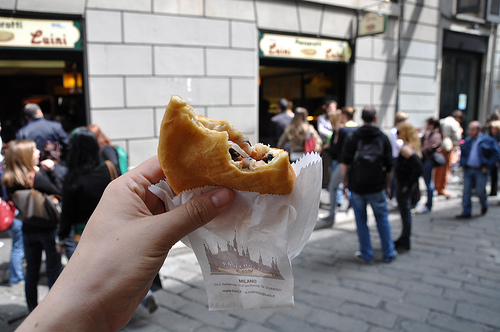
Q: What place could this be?
A: It is a street.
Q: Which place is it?
A: It is a street.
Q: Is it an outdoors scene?
A: Yes, it is outdoors.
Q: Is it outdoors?
A: Yes, it is outdoors.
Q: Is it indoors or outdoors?
A: It is outdoors.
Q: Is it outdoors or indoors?
A: It is outdoors.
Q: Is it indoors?
A: No, it is outdoors.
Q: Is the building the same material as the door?
A: No, the building is made of concrete and the door is made of glass.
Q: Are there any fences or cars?
A: No, there are no fences or cars.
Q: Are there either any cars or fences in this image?
A: No, there are no fences or cars.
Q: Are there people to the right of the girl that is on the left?
A: Yes, there is a person to the right of the girl.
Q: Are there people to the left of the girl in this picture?
A: No, the person is to the right of the girl.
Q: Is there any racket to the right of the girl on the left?
A: No, there is a person to the right of the girl.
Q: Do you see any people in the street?
A: Yes, there is a person in the street.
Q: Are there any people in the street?
A: Yes, there is a person in the street.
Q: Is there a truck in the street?
A: No, there is a person in the street.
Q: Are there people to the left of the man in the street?
A: Yes, there is a person to the left of the man.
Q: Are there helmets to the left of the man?
A: No, there is a person to the left of the man.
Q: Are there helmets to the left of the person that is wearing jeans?
A: No, there is a person to the left of the man.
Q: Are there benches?
A: No, there are no benches.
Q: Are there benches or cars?
A: No, there are no benches or cars.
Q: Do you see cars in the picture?
A: No, there are no cars.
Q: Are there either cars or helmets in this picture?
A: No, there are no cars or helmets.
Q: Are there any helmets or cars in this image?
A: No, there are no cars or helmets.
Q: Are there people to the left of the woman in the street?
A: Yes, there is a person to the left of the woman.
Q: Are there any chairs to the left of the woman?
A: No, there is a person to the left of the woman.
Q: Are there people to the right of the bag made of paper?
A: Yes, there is a person to the right of the bag.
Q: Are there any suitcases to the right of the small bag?
A: No, there is a person to the right of the bag.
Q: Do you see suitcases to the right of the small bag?
A: No, there is a person to the right of the bag.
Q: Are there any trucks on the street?
A: No, there is a person on the street.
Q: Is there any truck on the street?
A: No, there is a person on the street.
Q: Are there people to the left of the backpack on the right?
A: Yes, there is a person to the left of the backpack.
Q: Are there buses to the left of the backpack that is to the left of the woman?
A: No, there is a person to the left of the backpack.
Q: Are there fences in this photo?
A: No, there are no fences.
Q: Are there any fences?
A: No, there are no fences.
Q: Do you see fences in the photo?
A: No, there are no fences.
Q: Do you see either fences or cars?
A: No, there are no fences or cars.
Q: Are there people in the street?
A: Yes, there is a person in the street.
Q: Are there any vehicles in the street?
A: No, there is a person in the street.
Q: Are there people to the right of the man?
A: Yes, there is a person to the right of the man.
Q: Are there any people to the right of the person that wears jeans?
A: Yes, there is a person to the right of the man.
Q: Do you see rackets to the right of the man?
A: No, there is a person to the right of the man.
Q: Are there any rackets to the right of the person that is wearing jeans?
A: No, there is a person to the right of the man.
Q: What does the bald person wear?
A: The person wears a coat.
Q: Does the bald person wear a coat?
A: Yes, the person wears a coat.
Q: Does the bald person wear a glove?
A: No, the person wears a coat.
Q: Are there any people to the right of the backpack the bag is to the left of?
A: Yes, there is a person to the right of the backpack.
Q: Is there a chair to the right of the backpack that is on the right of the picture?
A: No, there is a person to the right of the backpack.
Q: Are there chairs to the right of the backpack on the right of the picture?
A: No, there is a person to the right of the backpack.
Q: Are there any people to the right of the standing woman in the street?
A: Yes, there is a person to the right of the woman.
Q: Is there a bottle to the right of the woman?
A: No, there is a person to the right of the woman.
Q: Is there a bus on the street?
A: No, there is a person on the street.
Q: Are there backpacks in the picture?
A: Yes, there is a backpack.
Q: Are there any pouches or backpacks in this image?
A: Yes, there is a backpack.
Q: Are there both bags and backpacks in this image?
A: Yes, there are both a backpack and a bag.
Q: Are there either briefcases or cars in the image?
A: No, there are no cars or briefcases.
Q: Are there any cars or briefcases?
A: No, there are no cars or briefcases.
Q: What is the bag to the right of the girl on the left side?
A: The bag is a backpack.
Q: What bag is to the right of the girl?
A: The bag is a backpack.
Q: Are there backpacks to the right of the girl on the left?
A: Yes, there is a backpack to the right of the girl.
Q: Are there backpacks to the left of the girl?
A: No, the backpack is to the right of the girl.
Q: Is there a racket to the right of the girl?
A: No, there is a backpack to the right of the girl.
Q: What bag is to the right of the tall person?
A: The bag is a backpack.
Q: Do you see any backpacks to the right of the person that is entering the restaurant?
A: Yes, there is a backpack to the right of the person.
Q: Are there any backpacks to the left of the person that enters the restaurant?
A: No, the backpack is to the right of the person.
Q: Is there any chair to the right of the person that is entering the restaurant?
A: No, there is a backpack to the right of the person.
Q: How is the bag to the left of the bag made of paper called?
A: The bag is a backpack.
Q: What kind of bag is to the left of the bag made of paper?
A: The bag is a backpack.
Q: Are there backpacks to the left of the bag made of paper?
A: Yes, there is a backpack to the left of the bag.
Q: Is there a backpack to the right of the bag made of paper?
A: No, the backpack is to the left of the bag.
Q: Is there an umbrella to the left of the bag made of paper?
A: No, there is a backpack to the left of the bag.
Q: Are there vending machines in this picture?
A: No, there are no vending machines.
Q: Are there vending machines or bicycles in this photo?
A: No, there are no vending machines or bicycles.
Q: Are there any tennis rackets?
A: No, there are no tennis rackets.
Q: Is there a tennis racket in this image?
A: No, there are no rackets.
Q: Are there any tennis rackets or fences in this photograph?
A: No, there are no tennis rackets or fences.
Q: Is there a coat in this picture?
A: Yes, there is a coat.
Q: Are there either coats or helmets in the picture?
A: Yes, there is a coat.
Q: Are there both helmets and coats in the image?
A: No, there is a coat but no helmets.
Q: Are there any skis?
A: No, there are no skis.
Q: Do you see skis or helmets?
A: No, there are no skis or helmets.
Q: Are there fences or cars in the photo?
A: No, there are no fences or cars.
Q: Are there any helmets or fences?
A: No, there are no fences or helmets.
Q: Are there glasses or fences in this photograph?
A: No, there are no fences or glasses.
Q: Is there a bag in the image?
A: Yes, there is a bag.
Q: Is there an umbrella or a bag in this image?
A: Yes, there is a bag.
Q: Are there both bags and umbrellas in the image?
A: No, there is a bag but no umbrellas.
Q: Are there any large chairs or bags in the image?
A: Yes, there is a large bag.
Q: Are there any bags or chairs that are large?
A: Yes, the bag is large.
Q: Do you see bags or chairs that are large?
A: Yes, the bag is large.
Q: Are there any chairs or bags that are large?
A: Yes, the bag is large.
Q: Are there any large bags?
A: Yes, there is a large bag.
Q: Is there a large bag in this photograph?
A: Yes, there is a large bag.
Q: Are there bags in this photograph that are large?
A: Yes, there is a large bag.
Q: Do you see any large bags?
A: Yes, there is a large bag.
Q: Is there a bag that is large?
A: Yes, there is a bag that is large.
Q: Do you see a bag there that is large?
A: Yes, there is a bag that is large.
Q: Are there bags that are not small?
A: Yes, there is a large bag.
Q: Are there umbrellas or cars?
A: No, there are no cars or umbrellas.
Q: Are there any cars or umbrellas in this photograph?
A: No, there are no cars or umbrellas.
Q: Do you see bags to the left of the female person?
A: Yes, there is a bag to the left of the person.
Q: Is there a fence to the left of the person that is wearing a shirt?
A: No, there is a bag to the left of the person.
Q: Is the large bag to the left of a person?
A: Yes, the bag is to the left of a person.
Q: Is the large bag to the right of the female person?
A: No, the bag is to the left of the person.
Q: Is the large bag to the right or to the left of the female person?
A: The bag is to the left of the person.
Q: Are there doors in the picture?
A: Yes, there is a door.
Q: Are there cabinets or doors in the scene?
A: Yes, there is a door.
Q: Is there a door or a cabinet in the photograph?
A: Yes, there is a door.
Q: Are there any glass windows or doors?
A: Yes, there is a glass door.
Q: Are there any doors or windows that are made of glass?
A: Yes, the door is made of glass.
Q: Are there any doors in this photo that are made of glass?
A: Yes, there is a door that is made of glass.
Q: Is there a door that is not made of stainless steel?
A: Yes, there is a door that is made of glass.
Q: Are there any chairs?
A: No, there are no chairs.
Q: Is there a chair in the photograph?
A: No, there are no chairs.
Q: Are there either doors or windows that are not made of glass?
A: No, there is a door but it is made of glass.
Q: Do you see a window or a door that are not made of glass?
A: No, there is a door but it is made of glass.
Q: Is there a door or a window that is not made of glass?
A: No, there is a door but it is made of glass.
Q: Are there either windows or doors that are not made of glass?
A: No, there is a door but it is made of glass.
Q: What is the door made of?
A: The door is made of glass.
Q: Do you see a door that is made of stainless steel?
A: No, there is a door but it is made of glass.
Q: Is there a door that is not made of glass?
A: No, there is a door but it is made of glass.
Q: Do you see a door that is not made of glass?
A: No, there is a door but it is made of glass.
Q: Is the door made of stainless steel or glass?
A: The door is made of glass.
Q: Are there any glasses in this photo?
A: No, there are no glasses.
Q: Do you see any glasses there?
A: No, there are no glasses.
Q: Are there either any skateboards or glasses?
A: No, there are no glasses or skateboards.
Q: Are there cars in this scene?
A: No, there are no cars.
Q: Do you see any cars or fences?
A: No, there are no cars or fences.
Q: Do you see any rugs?
A: No, there are no rugs.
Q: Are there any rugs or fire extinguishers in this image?
A: No, there are no rugs or fire extinguishers.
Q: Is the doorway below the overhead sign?
A: Yes, the doorway is below the sign.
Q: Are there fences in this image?
A: No, there are no fences.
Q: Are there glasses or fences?
A: No, there are no fences or glasses.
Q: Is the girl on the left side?
A: Yes, the girl is on the left of the image.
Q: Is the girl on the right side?
A: No, the girl is on the left of the image.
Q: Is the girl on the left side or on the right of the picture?
A: The girl is on the left of the image.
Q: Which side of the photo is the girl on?
A: The girl is on the left of the image.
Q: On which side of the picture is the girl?
A: The girl is on the left of the image.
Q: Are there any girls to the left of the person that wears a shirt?
A: Yes, there is a girl to the left of the person.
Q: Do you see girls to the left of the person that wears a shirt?
A: Yes, there is a girl to the left of the person.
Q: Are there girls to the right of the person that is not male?
A: No, the girl is to the left of the person.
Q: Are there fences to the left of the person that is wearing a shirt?
A: No, there is a girl to the left of the person.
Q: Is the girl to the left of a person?
A: Yes, the girl is to the left of a person.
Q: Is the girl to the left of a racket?
A: No, the girl is to the left of a person.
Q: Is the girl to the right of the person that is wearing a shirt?
A: No, the girl is to the left of the person.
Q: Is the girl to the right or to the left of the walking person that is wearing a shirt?
A: The girl is to the left of the person.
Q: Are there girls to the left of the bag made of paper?
A: Yes, there is a girl to the left of the bag.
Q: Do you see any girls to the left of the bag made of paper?
A: Yes, there is a girl to the left of the bag.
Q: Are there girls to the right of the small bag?
A: No, the girl is to the left of the bag.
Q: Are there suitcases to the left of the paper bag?
A: No, there is a girl to the left of the bag.